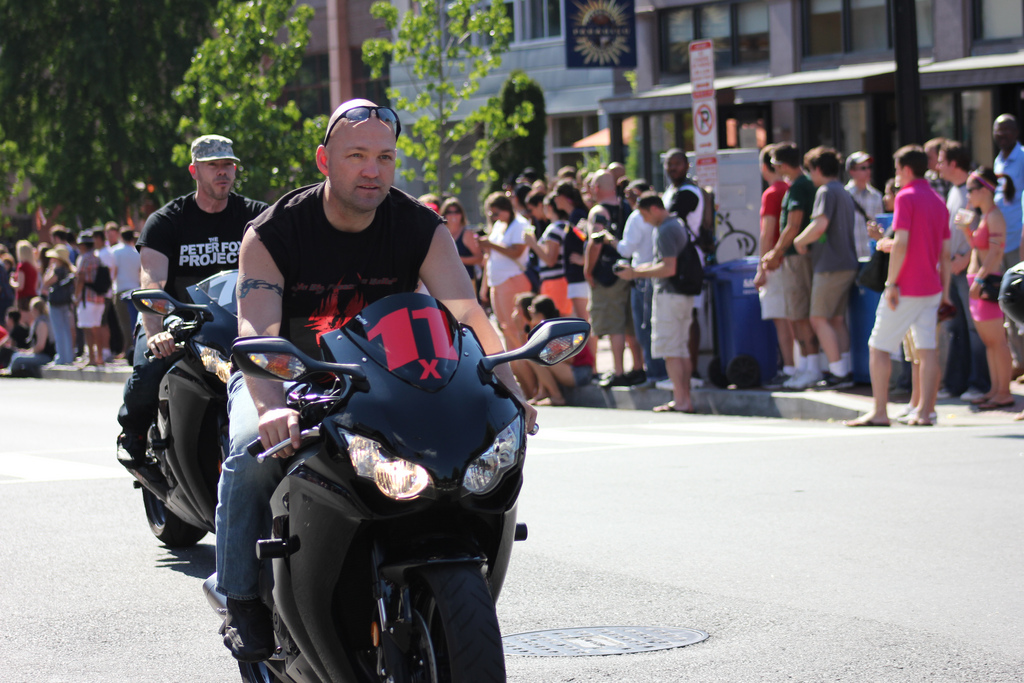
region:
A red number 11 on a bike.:
[362, 307, 457, 374]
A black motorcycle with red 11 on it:
[204, 292, 588, 681]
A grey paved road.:
[5, 361, 1021, 681]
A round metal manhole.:
[504, 618, 708, 657]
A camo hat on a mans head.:
[185, 134, 240, 169]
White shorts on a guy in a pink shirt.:
[866, 285, 940, 353]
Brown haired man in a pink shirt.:
[851, 147, 951, 426]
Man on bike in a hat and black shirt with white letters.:
[115, 134, 270, 461]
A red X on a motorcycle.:
[419, 353, 440, 380]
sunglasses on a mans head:
[330, 101, 404, 155]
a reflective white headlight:
[368, 455, 426, 494]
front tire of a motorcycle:
[333, 500, 515, 679]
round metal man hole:
[504, 608, 710, 662]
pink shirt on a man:
[886, 185, 953, 290]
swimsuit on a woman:
[959, 203, 1013, 324]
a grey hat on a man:
[189, 131, 241, 167]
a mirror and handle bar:
[498, 319, 593, 368]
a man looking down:
[634, 188, 702, 408]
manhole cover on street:
[501, 622, 711, 660]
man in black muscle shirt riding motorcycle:
[213, 97, 537, 661]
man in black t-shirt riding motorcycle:
[118, 133, 274, 495]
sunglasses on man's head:
[320, 105, 400, 147]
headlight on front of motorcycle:
[373, 455, 430, 498]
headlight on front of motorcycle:
[459, 443, 501, 489]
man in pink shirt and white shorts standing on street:
[846, 142, 951, 424]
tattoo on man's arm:
[234, 277, 283, 303]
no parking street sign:
[691, 97, 718, 154]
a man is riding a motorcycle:
[212, 98, 590, 680]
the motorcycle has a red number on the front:
[239, 290, 587, 680]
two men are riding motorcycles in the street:
[117, 127, 416, 595]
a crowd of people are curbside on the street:
[9, 141, 1022, 427]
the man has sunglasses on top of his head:
[313, 94, 408, 216]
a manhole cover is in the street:
[501, 614, 717, 663]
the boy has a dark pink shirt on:
[847, 145, 955, 418]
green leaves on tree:
[371, 8, 539, 185]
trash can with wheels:
[693, 259, 779, 387]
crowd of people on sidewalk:
[0, 111, 1018, 425]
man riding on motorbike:
[218, 97, 589, 677]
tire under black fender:
[387, 537, 506, 678]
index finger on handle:
[244, 400, 327, 464]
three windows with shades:
[661, 5, 769, 76]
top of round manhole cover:
[506, 617, 709, 660]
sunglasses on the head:
[286, 86, 436, 238]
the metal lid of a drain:
[511, 603, 711, 675]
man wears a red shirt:
[858, 131, 965, 445]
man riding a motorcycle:
[197, 86, 604, 675]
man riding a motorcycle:
[111, 119, 261, 555]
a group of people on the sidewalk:
[495, 102, 1015, 431]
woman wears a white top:
[470, 175, 538, 325]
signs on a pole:
[677, 25, 737, 212]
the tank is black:
[246, 169, 452, 338]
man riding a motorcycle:
[247, 104, 580, 674]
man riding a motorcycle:
[115, 106, 280, 572]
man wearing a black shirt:
[112, 188, 278, 305]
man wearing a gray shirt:
[640, 201, 694, 287]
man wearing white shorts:
[864, 280, 957, 357]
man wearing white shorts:
[639, 280, 693, 376]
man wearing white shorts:
[746, 252, 800, 330]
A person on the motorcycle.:
[252, 94, 480, 409]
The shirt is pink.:
[893, 186, 957, 282]